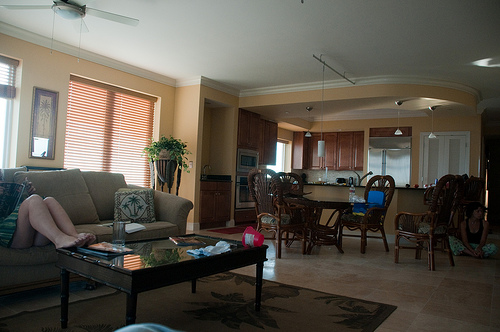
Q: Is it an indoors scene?
A: Yes, it is indoors.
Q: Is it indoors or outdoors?
A: It is indoors.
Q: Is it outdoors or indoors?
A: It is indoors.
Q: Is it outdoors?
A: No, it is indoors.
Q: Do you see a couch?
A: Yes, there is a couch.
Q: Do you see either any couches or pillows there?
A: Yes, there is a couch.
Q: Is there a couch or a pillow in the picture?
A: Yes, there is a couch.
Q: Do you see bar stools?
A: No, there are no bar stools.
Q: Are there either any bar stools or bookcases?
A: No, there are no bar stools or bookcases.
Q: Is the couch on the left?
A: Yes, the couch is on the left of the image.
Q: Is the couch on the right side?
A: No, the couch is on the left of the image.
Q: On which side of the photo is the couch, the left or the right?
A: The couch is on the left of the image.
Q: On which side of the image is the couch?
A: The couch is on the left of the image.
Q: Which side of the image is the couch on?
A: The couch is on the left of the image.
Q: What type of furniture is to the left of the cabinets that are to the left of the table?
A: The piece of furniture is a couch.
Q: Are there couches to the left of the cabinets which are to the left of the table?
A: Yes, there is a couch to the left of the cabinets.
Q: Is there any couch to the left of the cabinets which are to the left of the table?
A: Yes, there is a couch to the left of the cabinets.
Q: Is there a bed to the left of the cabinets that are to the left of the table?
A: No, there is a couch to the left of the cabinets.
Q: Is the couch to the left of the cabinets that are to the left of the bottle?
A: Yes, the couch is to the left of the cabinets.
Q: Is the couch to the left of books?
A: No, the couch is to the left of the cabinets.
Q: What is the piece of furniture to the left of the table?
A: The piece of furniture is a couch.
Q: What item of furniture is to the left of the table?
A: The piece of furniture is a couch.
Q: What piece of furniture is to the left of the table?
A: The piece of furniture is a couch.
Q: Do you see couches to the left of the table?
A: Yes, there is a couch to the left of the table.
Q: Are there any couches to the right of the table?
A: No, the couch is to the left of the table.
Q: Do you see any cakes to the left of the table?
A: No, there is a couch to the left of the table.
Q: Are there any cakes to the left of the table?
A: No, there is a couch to the left of the table.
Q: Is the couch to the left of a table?
A: Yes, the couch is to the left of a table.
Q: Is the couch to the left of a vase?
A: No, the couch is to the left of a table.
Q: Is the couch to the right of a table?
A: No, the couch is to the left of a table.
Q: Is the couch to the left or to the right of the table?
A: The couch is to the left of the table.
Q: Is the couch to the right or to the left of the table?
A: The couch is to the left of the table.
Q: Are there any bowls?
A: No, there are no bowls.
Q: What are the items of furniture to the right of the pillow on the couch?
A: The pieces of furniture are cabinets.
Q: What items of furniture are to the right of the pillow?
A: The pieces of furniture are cabinets.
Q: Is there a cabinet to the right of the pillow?
A: Yes, there are cabinets to the right of the pillow.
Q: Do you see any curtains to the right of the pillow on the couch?
A: No, there are cabinets to the right of the pillow.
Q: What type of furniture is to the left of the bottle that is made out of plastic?
A: The pieces of furniture are cabinets.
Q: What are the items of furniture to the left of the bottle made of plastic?
A: The pieces of furniture are cabinets.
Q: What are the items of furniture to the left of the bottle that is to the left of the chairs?
A: The pieces of furniture are cabinets.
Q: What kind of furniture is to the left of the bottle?
A: The pieces of furniture are cabinets.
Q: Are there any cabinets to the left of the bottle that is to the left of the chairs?
A: Yes, there are cabinets to the left of the bottle.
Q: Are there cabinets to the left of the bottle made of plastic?
A: Yes, there are cabinets to the left of the bottle.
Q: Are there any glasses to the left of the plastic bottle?
A: No, there are cabinets to the left of the bottle.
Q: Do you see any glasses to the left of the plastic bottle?
A: No, there are cabinets to the left of the bottle.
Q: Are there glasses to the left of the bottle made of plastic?
A: No, there are cabinets to the left of the bottle.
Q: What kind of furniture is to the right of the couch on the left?
A: The pieces of furniture are cabinets.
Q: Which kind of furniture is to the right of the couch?
A: The pieces of furniture are cabinets.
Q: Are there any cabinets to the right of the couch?
A: Yes, there are cabinets to the right of the couch.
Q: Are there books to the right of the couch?
A: No, there are cabinets to the right of the couch.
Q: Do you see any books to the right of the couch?
A: No, there are cabinets to the right of the couch.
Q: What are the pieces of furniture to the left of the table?
A: The pieces of furniture are cabinets.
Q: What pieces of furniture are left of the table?
A: The pieces of furniture are cabinets.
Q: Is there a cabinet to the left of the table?
A: Yes, there are cabinets to the left of the table.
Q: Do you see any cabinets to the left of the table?
A: Yes, there are cabinets to the left of the table.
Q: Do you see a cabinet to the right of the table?
A: No, the cabinets are to the left of the table.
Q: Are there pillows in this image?
A: Yes, there is a pillow.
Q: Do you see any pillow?
A: Yes, there is a pillow.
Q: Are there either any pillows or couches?
A: Yes, there is a pillow.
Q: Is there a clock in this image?
A: No, there are no clocks.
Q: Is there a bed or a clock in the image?
A: No, there are no clocks or beds.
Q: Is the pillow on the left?
A: Yes, the pillow is on the left of the image.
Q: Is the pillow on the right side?
A: No, the pillow is on the left of the image.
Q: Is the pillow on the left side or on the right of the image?
A: The pillow is on the left of the image.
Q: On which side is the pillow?
A: The pillow is on the left of the image.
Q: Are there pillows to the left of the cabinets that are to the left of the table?
A: Yes, there is a pillow to the left of the cabinets.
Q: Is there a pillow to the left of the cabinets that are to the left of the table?
A: Yes, there is a pillow to the left of the cabinets.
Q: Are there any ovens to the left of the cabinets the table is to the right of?
A: No, there is a pillow to the left of the cabinets.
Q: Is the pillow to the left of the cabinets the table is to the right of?
A: Yes, the pillow is to the left of the cabinets.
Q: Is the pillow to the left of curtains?
A: No, the pillow is to the left of the cabinets.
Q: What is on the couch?
A: The pillow is on the couch.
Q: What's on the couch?
A: The pillow is on the couch.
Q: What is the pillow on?
A: The pillow is on the couch.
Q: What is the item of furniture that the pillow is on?
A: The piece of furniture is a couch.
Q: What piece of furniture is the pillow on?
A: The pillow is on the couch.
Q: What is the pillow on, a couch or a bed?
A: The pillow is on a couch.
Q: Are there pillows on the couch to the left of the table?
A: Yes, there is a pillow on the couch.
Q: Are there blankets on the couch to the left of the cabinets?
A: No, there is a pillow on the couch.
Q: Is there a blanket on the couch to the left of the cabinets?
A: No, there is a pillow on the couch.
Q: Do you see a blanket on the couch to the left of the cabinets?
A: No, there is a pillow on the couch.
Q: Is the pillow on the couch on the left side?
A: Yes, the pillow is on the couch.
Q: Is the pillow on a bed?
A: No, the pillow is on the couch.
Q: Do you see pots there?
A: No, there are no pots.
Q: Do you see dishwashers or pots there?
A: No, there are no pots or dishwashers.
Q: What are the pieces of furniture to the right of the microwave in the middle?
A: The pieces of furniture are cabinets.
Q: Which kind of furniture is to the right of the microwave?
A: The pieces of furniture are cabinets.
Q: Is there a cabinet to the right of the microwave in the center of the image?
A: Yes, there are cabinets to the right of the microwave.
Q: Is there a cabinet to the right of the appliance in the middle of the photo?
A: Yes, there are cabinets to the right of the microwave.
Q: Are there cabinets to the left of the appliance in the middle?
A: No, the cabinets are to the right of the microwave.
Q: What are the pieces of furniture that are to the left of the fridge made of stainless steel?
A: The pieces of furniture are cabinets.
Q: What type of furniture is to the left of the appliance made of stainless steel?
A: The pieces of furniture are cabinets.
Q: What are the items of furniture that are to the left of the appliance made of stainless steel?
A: The pieces of furniture are cabinets.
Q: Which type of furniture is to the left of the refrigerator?
A: The pieces of furniture are cabinets.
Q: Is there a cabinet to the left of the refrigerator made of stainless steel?
A: Yes, there are cabinets to the left of the freezer.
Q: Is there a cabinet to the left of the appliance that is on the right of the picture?
A: Yes, there are cabinets to the left of the freezer.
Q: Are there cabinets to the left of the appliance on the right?
A: Yes, there are cabinets to the left of the freezer.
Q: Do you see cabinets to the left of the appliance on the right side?
A: Yes, there are cabinets to the left of the freezer.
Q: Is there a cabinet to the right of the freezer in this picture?
A: No, the cabinets are to the left of the freezer.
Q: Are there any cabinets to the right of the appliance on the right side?
A: No, the cabinets are to the left of the freezer.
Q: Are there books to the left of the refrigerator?
A: No, there are cabinets to the left of the refrigerator.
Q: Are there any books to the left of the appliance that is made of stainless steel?
A: No, there are cabinets to the left of the refrigerator.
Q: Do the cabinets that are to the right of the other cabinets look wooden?
A: Yes, the cabinets are wooden.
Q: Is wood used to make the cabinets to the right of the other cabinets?
A: Yes, the cabinets are made of wood.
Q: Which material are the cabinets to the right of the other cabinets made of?
A: The cabinets are made of wood.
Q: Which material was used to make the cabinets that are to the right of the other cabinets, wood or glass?
A: The cabinets are made of wood.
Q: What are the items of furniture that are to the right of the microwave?
A: The pieces of furniture are cabinets.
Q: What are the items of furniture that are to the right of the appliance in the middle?
A: The pieces of furniture are cabinets.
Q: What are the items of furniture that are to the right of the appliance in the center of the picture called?
A: The pieces of furniture are cabinets.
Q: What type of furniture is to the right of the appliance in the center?
A: The pieces of furniture are cabinets.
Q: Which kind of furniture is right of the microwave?
A: The pieces of furniture are cabinets.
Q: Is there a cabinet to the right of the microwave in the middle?
A: Yes, there are cabinets to the right of the microwave.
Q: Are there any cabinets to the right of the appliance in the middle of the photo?
A: Yes, there are cabinets to the right of the microwave.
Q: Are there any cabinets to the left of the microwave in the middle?
A: No, the cabinets are to the right of the microwave.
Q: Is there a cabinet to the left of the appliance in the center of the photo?
A: No, the cabinets are to the right of the microwave.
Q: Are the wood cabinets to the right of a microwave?
A: Yes, the cabinets are to the right of a microwave.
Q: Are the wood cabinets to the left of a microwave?
A: No, the cabinets are to the right of a microwave.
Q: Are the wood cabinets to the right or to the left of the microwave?
A: The cabinets are to the right of the microwave.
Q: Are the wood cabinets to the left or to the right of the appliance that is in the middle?
A: The cabinets are to the right of the microwave.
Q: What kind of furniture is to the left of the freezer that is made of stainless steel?
A: The pieces of furniture are cabinets.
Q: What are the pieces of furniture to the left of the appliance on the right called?
A: The pieces of furniture are cabinets.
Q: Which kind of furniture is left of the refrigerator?
A: The pieces of furniture are cabinets.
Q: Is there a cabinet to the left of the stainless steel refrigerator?
A: Yes, there are cabinets to the left of the fridge.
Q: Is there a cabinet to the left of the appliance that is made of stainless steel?
A: Yes, there are cabinets to the left of the fridge.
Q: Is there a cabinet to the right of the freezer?
A: No, the cabinets are to the left of the freezer.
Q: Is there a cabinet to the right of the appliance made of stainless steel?
A: No, the cabinets are to the left of the freezer.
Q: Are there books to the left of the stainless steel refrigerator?
A: No, there are cabinets to the left of the freezer.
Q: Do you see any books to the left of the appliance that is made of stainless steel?
A: No, there are cabinets to the left of the freezer.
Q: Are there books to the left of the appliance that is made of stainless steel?
A: No, there are cabinets to the left of the freezer.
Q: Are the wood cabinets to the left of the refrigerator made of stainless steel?
A: Yes, the cabinets are to the left of the fridge.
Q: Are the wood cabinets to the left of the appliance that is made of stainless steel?
A: Yes, the cabinets are to the left of the fridge.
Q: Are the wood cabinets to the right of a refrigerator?
A: No, the cabinets are to the left of a refrigerator.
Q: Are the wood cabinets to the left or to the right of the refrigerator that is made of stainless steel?
A: The cabinets are to the left of the refrigerator.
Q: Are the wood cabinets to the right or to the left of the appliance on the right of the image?
A: The cabinets are to the left of the refrigerator.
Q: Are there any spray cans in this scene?
A: No, there are no spray cans.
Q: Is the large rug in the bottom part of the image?
A: Yes, the rug is in the bottom of the image.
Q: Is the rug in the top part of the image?
A: No, the rug is in the bottom of the image.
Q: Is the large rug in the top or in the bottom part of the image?
A: The rug is in the bottom of the image.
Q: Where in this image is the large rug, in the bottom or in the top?
A: The rug is in the bottom of the image.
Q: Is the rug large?
A: Yes, the rug is large.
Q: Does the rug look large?
A: Yes, the rug is large.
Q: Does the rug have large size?
A: Yes, the rug is large.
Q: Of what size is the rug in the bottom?
A: The rug is large.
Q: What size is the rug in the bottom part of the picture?
A: The rug is large.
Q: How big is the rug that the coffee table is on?
A: The rug is large.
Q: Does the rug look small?
A: No, the rug is large.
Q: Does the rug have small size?
A: No, the rug is large.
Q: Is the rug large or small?
A: The rug is large.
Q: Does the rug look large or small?
A: The rug is large.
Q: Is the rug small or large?
A: The rug is large.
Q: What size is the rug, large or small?
A: The rug is large.